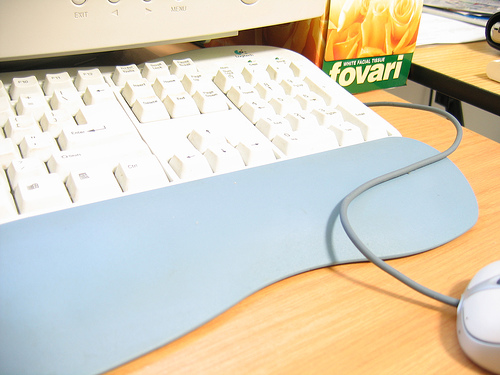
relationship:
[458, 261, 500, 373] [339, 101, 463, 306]
mouse has cord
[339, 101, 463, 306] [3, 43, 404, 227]
cord on keyboard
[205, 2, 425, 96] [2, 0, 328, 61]
box next to monitor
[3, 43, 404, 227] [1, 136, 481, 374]
keyboard has pad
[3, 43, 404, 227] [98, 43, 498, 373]
keyboard on table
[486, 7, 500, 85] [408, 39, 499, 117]
camera on table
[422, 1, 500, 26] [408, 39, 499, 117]
notebook on table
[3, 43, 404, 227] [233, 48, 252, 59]
keyboard has logo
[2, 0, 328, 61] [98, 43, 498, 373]
monitor on table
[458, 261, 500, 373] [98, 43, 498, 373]
mouse on table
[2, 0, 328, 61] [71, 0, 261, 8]
monitor has buttons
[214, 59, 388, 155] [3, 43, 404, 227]
number pad on keyboard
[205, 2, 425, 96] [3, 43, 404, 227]
box next to keyboard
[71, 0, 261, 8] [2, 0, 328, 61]
buttons on monitor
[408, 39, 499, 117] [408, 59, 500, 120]
table has trim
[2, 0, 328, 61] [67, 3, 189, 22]
monitor has button labels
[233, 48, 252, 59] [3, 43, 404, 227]
logo on keyboard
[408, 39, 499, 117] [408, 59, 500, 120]
table has edge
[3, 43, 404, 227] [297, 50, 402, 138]
keyboard has edge